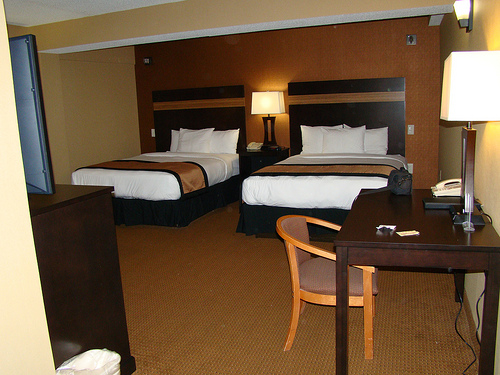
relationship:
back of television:
[9, 39, 48, 192] [6, 32, 59, 199]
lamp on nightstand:
[248, 89, 284, 150] [235, 148, 292, 216]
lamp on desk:
[440, 48, 500, 228] [332, 186, 499, 374]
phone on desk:
[428, 177, 465, 197] [332, 186, 499, 374]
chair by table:
[271, 210, 382, 363] [332, 186, 499, 374]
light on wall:
[450, 0, 475, 37] [441, 1, 499, 375]